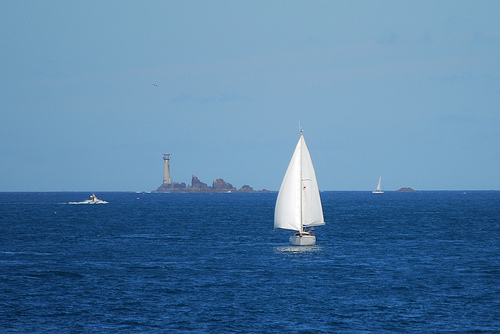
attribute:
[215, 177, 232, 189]
building — distant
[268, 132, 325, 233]
white sail — large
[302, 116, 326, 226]
sail — white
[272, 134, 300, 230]
sail — white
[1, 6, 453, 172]
sky — blue 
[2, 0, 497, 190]
blue sky — blue 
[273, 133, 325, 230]
white sail — white 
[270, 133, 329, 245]
sail boat — white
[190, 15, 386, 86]
clouds — white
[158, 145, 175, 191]
tower — background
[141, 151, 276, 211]
island — distant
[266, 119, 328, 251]
boat — white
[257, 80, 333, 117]
clouds — white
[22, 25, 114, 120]
sky — blue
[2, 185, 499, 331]
sea — blue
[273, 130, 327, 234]
sail — white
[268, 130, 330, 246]
boat — white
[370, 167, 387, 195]
boat — white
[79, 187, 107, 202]
boat — white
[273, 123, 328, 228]
sails — white, unfurled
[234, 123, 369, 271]
sail boat — white 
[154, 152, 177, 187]
lighthouse — large, gray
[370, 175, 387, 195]
sailboat — white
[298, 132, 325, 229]
sail — white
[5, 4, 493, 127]
sky — blue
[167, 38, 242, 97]
clouds — white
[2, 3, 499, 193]
sky — cloudless, blue, clear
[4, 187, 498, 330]
water — blue, ocean, large